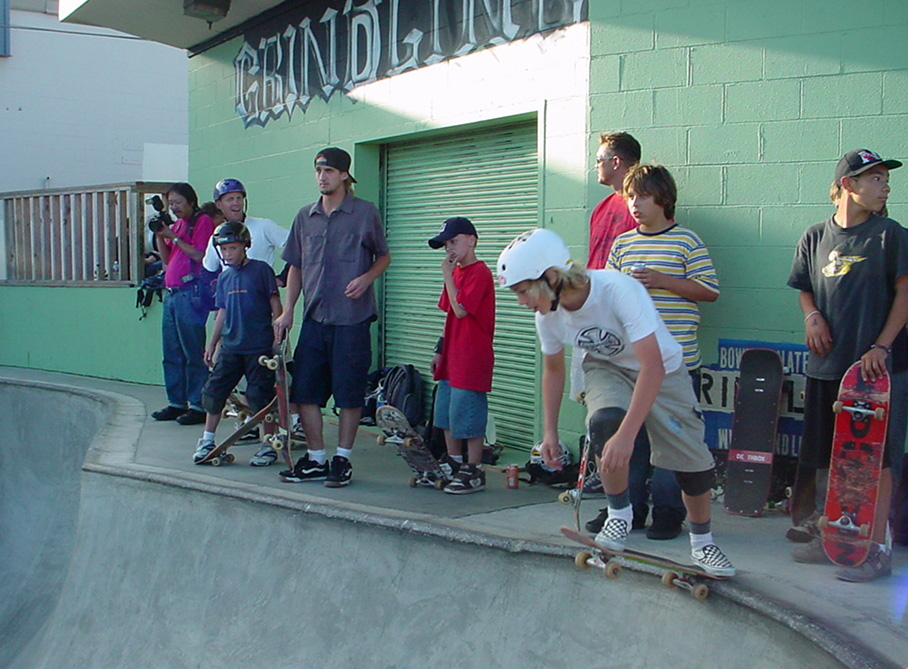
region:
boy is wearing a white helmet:
[492, 223, 743, 605]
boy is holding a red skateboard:
[777, 144, 900, 587]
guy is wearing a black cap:
[263, 144, 394, 495]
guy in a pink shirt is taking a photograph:
[135, 178, 224, 434]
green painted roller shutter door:
[376, 110, 547, 466]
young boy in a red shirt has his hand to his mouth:
[415, 211, 501, 498]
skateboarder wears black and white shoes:
[492, 223, 743, 601]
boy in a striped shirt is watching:
[588, 158, 725, 544]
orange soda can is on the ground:
[502, 458, 524, 493]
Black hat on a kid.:
[426, 215, 479, 248]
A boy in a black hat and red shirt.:
[411, 215, 496, 495]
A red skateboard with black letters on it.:
[818, 355, 891, 566]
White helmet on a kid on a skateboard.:
[494, 226, 577, 288]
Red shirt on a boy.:
[433, 260, 497, 392]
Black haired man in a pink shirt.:
[151, 182, 214, 425]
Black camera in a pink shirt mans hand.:
[140, 195, 176, 236]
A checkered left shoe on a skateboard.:
[691, 544, 738, 579]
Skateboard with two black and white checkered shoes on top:
[560, 520, 735, 600]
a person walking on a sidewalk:
[195, 212, 300, 448]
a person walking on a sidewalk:
[573, 128, 662, 270]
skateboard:
[730, 329, 785, 519]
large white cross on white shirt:
[570, 320, 620, 352]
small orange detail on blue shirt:
[221, 285, 245, 292]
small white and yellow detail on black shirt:
[819, 246, 863, 274]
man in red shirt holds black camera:
[142, 180, 205, 422]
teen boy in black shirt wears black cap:
[783, 146, 903, 575]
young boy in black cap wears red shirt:
[426, 215, 484, 489]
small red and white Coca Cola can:
[499, 459, 515, 488]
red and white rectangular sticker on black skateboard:
[725, 444, 769, 463]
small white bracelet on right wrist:
[801, 304, 812, 316]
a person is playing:
[460, 212, 750, 585]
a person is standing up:
[505, 225, 730, 580]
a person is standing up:
[792, 137, 900, 562]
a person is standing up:
[607, 166, 717, 536]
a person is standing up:
[572, 134, 657, 271]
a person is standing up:
[424, 224, 494, 493]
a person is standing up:
[280, 147, 388, 492]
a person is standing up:
[185, 223, 288, 469]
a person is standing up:
[206, 176, 286, 443]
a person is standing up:
[144, 175, 225, 427]